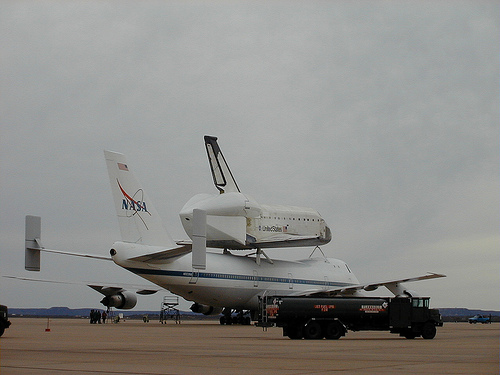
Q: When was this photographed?
A: Daytime.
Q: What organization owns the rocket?
A: Nasa.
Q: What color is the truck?
A: Black.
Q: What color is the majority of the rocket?
A: White.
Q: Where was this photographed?
A: Airport.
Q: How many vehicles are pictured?
A: Two.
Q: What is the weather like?
A: Cloudy.